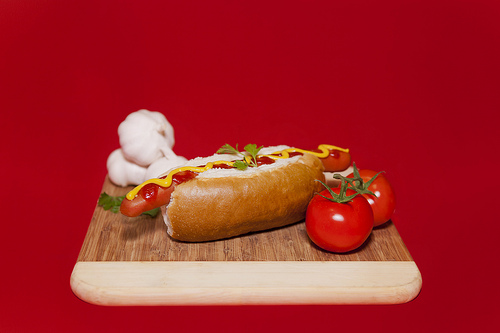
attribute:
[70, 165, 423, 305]
cutting board — small, wooden, brown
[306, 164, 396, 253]
tomatoes — whole, red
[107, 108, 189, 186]
garlic — whole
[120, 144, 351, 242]
hot dog — long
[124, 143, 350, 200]
mustard — drizzled, yellow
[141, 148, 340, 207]
ketchup — drizzled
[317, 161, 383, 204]
stems — green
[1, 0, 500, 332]
background — red